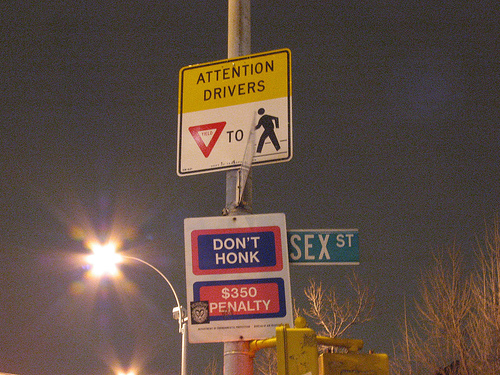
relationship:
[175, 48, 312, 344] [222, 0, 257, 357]
signs on pole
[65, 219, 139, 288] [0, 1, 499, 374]
light in sky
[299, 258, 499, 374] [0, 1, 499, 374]
branches in sky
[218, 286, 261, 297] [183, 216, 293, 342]
dollar amount on sign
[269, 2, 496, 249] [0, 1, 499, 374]
clouds in sky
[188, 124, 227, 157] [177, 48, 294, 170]
yield sign on sign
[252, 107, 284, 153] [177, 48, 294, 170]
person on sign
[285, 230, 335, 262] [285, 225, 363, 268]
word sex on sign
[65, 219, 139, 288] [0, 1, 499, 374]
light illuminating sky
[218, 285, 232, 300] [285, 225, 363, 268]
$ on sign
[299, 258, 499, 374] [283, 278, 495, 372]
trees in back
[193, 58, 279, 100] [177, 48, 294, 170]
words on sign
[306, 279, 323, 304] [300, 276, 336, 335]
part of branch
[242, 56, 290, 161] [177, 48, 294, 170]
part of post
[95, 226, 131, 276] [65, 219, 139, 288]
part of light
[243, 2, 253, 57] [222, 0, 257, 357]
edge of pole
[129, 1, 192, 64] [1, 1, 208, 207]
part of cloud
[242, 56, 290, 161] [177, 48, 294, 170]
part of sign post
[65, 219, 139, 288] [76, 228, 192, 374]
lamp to street light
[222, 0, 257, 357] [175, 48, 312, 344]
pole has signs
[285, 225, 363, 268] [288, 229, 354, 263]
sign says sex st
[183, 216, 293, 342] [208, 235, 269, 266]
sign giving directions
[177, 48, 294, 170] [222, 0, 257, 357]
sign on pole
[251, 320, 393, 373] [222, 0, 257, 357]
signals on pole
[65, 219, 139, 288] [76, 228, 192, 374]
light on street light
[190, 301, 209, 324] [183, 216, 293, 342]
badge on sign